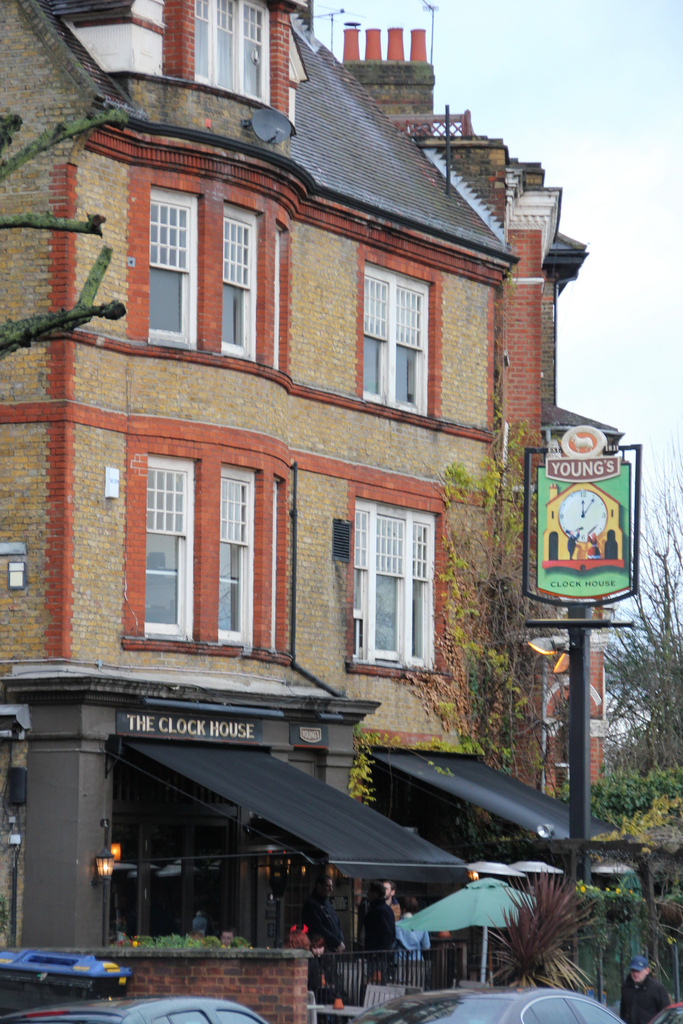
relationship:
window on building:
[217, 464, 259, 642] [9, 6, 587, 1021]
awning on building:
[365, 735, 619, 855] [258, 2, 602, 1009]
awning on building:
[109, 748, 469, 883] [9, 6, 587, 1021]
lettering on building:
[118, 699, 267, 736] [9, 6, 587, 1021]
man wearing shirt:
[619, 950, 670, 1021] [617, 982, 666, 1021]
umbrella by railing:
[398, 878, 537, 937] [304, 943, 522, 1005]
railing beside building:
[309, 925, 649, 1021] [9, 6, 587, 1021]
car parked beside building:
[364, 970, 639, 1022] [1, 9, 659, 980]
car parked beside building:
[0, 952, 130, 1021] [1, 9, 659, 980]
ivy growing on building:
[292, 284, 580, 837] [1, 9, 659, 980]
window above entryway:
[140, 451, 199, 640] [4, 673, 380, 943]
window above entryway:
[220, 465, 250, 643] [4, 673, 380, 943]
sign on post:
[517, 424, 643, 630] [566, 608, 595, 836]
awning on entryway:
[109, 734, 472, 883] [4, 673, 380, 943]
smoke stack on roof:
[410, 32, 428, 64] [1, 0, 588, 257]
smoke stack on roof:
[382, 24, 408, 60] [1, 0, 588, 257]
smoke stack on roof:
[363, 26, 384, 59] [1, 0, 588, 257]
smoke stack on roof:
[340, 25, 362, 61] [1, 0, 588, 257]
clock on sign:
[553, 487, 616, 546] [517, 424, 643, 630]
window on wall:
[150, 188, 200, 350] [70, 151, 497, 730]